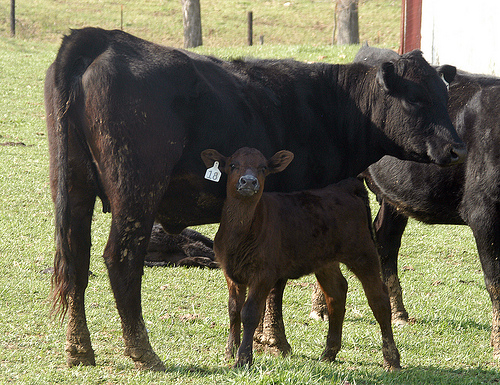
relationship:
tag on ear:
[202, 158, 226, 186] [202, 147, 227, 178]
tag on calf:
[202, 158, 226, 186] [196, 142, 415, 371]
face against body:
[380, 47, 470, 168] [350, 31, 499, 362]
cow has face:
[46, 21, 470, 371] [380, 47, 470, 168]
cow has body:
[342, 37, 500, 365] [350, 31, 499, 362]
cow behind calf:
[46, 21, 470, 371] [196, 142, 415, 371]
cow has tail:
[46, 21, 470, 371] [44, 21, 98, 327]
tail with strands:
[44, 21, 98, 327] [44, 210, 80, 321]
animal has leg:
[43, 22, 465, 373] [101, 170, 176, 372]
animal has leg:
[43, 22, 465, 373] [43, 85, 104, 378]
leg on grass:
[101, 170, 176, 372] [5, 0, 500, 379]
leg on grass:
[43, 85, 104, 378] [5, 0, 500, 379]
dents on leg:
[112, 210, 150, 273] [101, 170, 176, 372]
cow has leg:
[46, 21, 470, 371] [101, 170, 176, 372]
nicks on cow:
[113, 210, 148, 271] [46, 21, 470, 371]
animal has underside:
[342, 37, 500, 365] [366, 148, 469, 239]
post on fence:
[245, 5, 259, 51] [5, 2, 420, 49]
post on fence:
[6, 0, 23, 41] [5, 2, 420, 49]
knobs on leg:
[113, 209, 156, 270] [101, 170, 176, 372]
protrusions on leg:
[125, 103, 174, 221] [101, 170, 176, 372]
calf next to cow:
[196, 142, 415, 371] [46, 21, 470, 371]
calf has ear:
[196, 142, 415, 371] [202, 147, 227, 178]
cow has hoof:
[46, 21, 470, 371] [126, 349, 167, 373]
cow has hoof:
[46, 21, 470, 371] [64, 343, 97, 372]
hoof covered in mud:
[126, 349, 167, 373] [119, 331, 169, 381]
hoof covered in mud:
[64, 343, 97, 372] [64, 319, 98, 372]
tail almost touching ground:
[44, 21, 98, 327] [5, 0, 500, 379]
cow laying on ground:
[146, 219, 230, 275] [5, 0, 500, 379]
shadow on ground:
[155, 305, 500, 381] [5, 0, 500, 379]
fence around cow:
[5, 2, 420, 49] [46, 21, 470, 371]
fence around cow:
[5, 2, 420, 49] [342, 37, 500, 365]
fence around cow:
[5, 2, 420, 49] [146, 219, 230, 275]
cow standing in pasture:
[46, 21, 470, 371] [2, 4, 499, 375]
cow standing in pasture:
[342, 37, 500, 365] [2, 4, 499, 375]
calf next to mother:
[196, 142, 415, 371] [46, 21, 470, 371]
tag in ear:
[202, 158, 226, 186] [202, 147, 227, 178]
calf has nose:
[196, 142, 415, 371] [234, 167, 262, 201]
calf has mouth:
[196, 142, 415, 371] [238, 183, 261, 194]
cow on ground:
[146, 219, 230, 275] [5, 0, 500, 379]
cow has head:
[46, 21, 470, 371] [380, 47, 470, 168]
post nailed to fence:
[245, 5, 259, 51] [5, 2, 420, 49]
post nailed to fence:
[6, 0, 23, 41] [5, 2, 420, 49]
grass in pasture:
[5, 0, 500, 379] [2, 4, 499, 375]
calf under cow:
[196, 142, 415, 371] [46, 21, 470, 371]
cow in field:
[46, 21, 470, 371] [7, 3, 493, 378]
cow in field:
[342, 37, 500, 365] [7, 3, 493, 378]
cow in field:
[201, 131, 411, 373] [7, 3, 493, 378]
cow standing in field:
[201, 131, 411, 373] [7, 3, 493, 378]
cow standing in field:
[342, 37, 500, 365] [7, 3, 493, 378]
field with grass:
[7, 3, 493, 378] [5, 0, 500, 379]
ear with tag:
[202, 147, 227, 178] [202, 158, 226, 186]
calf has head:
[196, 142, 415, 371] [196, 144, 297, 209]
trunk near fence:
[335, 0, 363, 46] [5, 2, 420, 49]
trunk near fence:
[182, 2, 208, 50] [5, 2, 420, 49]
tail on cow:
[44, 21, 98, 327] [46, 21, 470, 371]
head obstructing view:
[371, 46, 466, 169] [6, 0, 497, 377]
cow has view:
[342, 37, 500, 365] [6, 0, 497, 377]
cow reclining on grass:
[146, 219, 230, 275] [5, 0, 500, 379]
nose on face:
[234, 167, 262, 201] [221, 142, 273, 200]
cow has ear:
[201, 131, 411, 373] [202, 147, 227, 178]